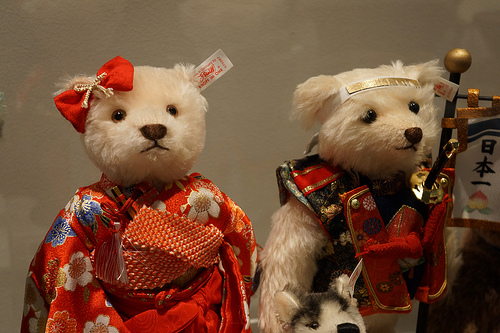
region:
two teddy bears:
[29, 48, 480, 328]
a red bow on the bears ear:
[46, 52, 157, 125]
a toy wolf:
[274, 271, 395, 331]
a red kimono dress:
[13, 180, 265, 330]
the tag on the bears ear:
[186, 47, 236, 92]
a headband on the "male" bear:
[323, 67, 460, 98]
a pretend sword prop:
[402, 135, 469, 213]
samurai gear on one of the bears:
[271, 155, 472, 305]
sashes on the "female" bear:
[82, 204, 224, 331]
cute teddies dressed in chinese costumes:
[26, 55, 496, 332]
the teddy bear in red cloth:
[257, 120, 422, 327]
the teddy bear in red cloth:
[76, 60, 291, 327]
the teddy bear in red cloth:
[47, 30, 284, 219]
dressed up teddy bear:
[44, 60, 277, 328]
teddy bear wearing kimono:
[44, 59, 239, 324]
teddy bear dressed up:
[288, 69, 478, 330]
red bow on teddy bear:
[37, 50, 225, 192]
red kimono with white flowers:
[33, 187, 258, 330]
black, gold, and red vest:
[277, 134, 467, 331]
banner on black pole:
[444, 63, 498, 228]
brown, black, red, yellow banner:
[411, 99, 494, 236]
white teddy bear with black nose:
[48, 37, 210, 182]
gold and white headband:
[295, 59, 460, 129]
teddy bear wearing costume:
[51, 59, 252, 331]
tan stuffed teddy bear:
[54, 60, 243, 332]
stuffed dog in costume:
[264, 66, 463, 327]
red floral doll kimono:
[33, 176, 255, 331]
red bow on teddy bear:
[53, 58, 133, 131]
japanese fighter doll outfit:
[281, 153, 457, 325]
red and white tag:
[191, 51, 233, 91]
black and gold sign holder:
[440, 48, 473, 208]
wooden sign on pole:
[455, 101, 499, 242]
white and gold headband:
[314, 75, 433, 106]